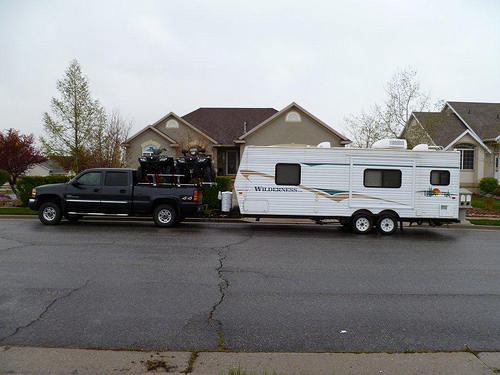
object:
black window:
[363, 168, 402, 188]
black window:
[430, 170, 451, 186]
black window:
[275, 163, 302, 186]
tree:
[0, 128, 47, 197]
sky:
[2, 0, 498, 165]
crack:
[205, 225, 254, 350]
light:
[194, 190, 203, 203]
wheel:
[352, 213, 373, 234]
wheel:
[376, 215, 398, 236]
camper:
[233, 145, 461, 235]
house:
[4, 156, 106, 187]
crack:
[180, 352, 197, 375]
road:
[0, 219, 498, 351]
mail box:
[459, 188, 473, 210]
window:
[273, 161, 301, 186]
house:
[400, 100, 500, 220]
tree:
[36, 58, 109, 173]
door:
[225, 150, 238, 175]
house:
[120, 102, 353, 210]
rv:
[234, 144, 460, 235]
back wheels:
[153, 204, 177, 228]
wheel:
[38, 202, 62, 226]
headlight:
[31, 188, 36, 198]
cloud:
[0, 0, 500, 158]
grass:
[0, 330, 500, 374]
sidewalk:
[0, 345, 500, 375]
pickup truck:
[29, 168, 218, 227]